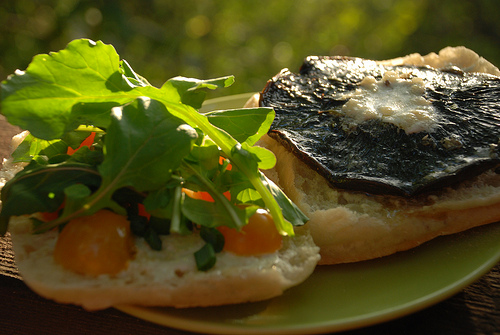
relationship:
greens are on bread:
[96, 68, 158, 129] [144, 244, 174, 283]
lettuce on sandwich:
[46, 63, 134, 95] [139, 266, 220, 301]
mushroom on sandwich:
[281, 61, 482, 184] [207, 250, 276, 290]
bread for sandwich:
[325, 196, 357, 229] [16, 39, 476, 313]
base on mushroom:
[360, 73, 416, 124] [267, 70, 319, 145]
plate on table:
[10, 23, 484, 321] [446, 297, 476, 325]